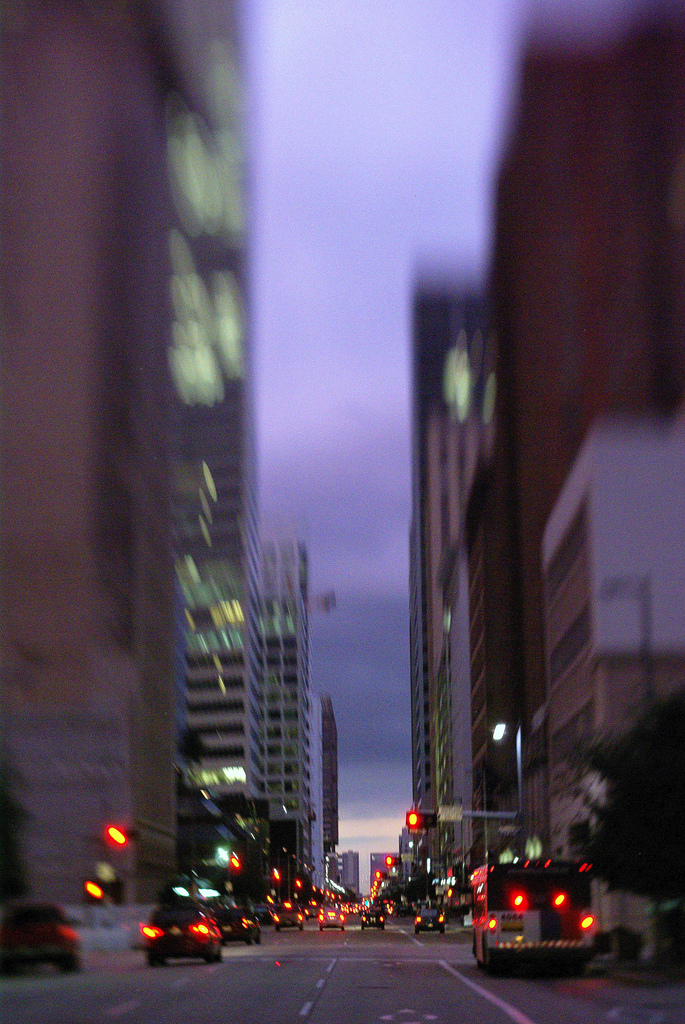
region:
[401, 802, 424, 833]
traffic signal is red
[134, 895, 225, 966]
tail lights on dark car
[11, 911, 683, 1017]
white lines on the road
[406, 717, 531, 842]
traffic light on metal pole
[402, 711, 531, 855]
white street light on metal pole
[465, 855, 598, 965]
striped rear bumper on bus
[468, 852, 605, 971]
tail lights on bus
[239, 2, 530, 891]
sky is faded lavender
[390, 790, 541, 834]
Street light currenty red.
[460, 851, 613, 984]
A city bus stopped on the street.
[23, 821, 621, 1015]
Cars on a city street.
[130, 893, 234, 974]
A red car stopped.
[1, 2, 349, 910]
Buildings on the side of the road.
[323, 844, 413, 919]
Buildings in the distance.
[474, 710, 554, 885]
Street light.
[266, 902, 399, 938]
Three cars waiting at a light.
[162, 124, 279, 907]
Lit windows on sky scraper.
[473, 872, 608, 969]
a bus waiting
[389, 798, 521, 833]
A red traffic light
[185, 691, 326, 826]
tall building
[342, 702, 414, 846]
Dark skies with clouds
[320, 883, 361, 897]
Street lights that are lit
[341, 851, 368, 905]
tall building in the distance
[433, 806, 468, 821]
A street sign on a traffic light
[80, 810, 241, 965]
Street light on red.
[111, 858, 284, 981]
Cars waiting on red light.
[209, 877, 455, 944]
Cars on the road.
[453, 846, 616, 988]
City bus at night.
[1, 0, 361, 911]
City skyline at night.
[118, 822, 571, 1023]
Road full of cars.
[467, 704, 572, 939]
Lit street lamp.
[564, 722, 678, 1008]
Tree growing on the side walk.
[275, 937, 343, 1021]
White dividing lines on the road.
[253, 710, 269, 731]
a window on the building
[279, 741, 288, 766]
a window on the building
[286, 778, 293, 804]
a window on the building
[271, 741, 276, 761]
a window on the building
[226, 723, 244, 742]
a window on the building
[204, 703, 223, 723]
a window on the building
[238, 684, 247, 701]
a window on the building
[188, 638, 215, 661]
a window on the building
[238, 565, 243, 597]
a window on the building